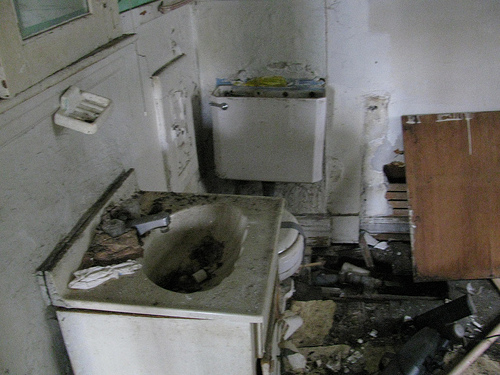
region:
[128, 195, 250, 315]
a dirty sink basin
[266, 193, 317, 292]
a dirty toilet taped closed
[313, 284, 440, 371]
rubble on the ground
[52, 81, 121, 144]
a white dirty soap holder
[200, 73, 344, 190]
a dirty back of a toilet tank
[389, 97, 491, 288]
a wooden panel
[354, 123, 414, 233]
a hole in a wall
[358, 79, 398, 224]
ruined drywall on a wall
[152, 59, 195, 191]
a dirty white wall panel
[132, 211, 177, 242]
a silver sink faucet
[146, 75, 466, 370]
Junk on the floor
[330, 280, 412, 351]
Junk on the floor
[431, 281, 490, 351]
Junk on the floor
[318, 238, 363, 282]
Junk on the floor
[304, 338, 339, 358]
Junk on the floor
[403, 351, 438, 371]
Junk on the floor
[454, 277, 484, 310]
Junk on the floor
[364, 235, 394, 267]
Junk on the floor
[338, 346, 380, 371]
Junk on the floor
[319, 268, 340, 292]
Junk on the floor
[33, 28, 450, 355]
disgusting beat up bath room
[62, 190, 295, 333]
broken bath room sink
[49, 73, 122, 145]
broken bath room soap dish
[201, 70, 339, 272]
broken bath room toilet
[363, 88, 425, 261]
hole in the dry wall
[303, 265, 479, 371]
trash all over the bathroom floor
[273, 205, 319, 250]
duct tape holding toilet seat closed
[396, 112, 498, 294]
wood panel laying against wall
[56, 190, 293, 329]
busted up sing with garbage in it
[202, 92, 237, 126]
silver handle on toilet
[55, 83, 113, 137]
tilted soap dish on wall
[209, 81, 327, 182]
white tank with no lids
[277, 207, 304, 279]
edge of closed toilet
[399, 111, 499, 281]
wood square panel upright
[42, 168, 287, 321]
top of dirty sink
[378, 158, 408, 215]
hole in bathroom wall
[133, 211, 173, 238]
metal faucet over sink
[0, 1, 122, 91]
bottom of cabinet door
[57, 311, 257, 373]
side of sink vanity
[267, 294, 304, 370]
curled piece of peeling paint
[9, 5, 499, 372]
a dirty and broken bathroom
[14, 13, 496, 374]
a bathroom is demolished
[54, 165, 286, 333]
sink of bathroom is covered with dust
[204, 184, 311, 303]
a toilet behind a counter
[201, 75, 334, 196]
tank of toilet without a lid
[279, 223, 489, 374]
lots of debris on floor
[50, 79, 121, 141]
a dirty dish soap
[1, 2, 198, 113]
a window with white frame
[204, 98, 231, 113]
handle of a bathtub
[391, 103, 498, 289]
a brown board